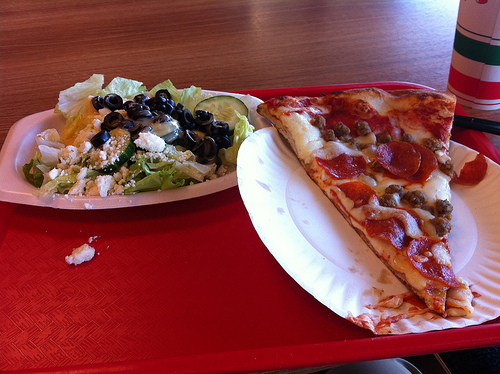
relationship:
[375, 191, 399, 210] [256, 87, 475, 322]
sausage on slice of pizza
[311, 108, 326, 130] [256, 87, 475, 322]
sausage on slice of pizza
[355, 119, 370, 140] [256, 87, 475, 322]
sausage on slice of pizza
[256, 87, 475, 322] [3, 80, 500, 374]
slice of pizza on tray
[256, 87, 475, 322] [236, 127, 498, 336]
slice of pizza on plate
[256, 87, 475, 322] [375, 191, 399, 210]
slice of pizza has sausage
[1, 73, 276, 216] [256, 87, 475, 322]
plate of salad next to slice of pizza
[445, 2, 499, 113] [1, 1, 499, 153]
cup sitting on table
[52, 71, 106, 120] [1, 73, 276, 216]
lettuce in plate of salad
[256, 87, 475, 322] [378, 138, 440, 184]
slice of pizza has pepperoni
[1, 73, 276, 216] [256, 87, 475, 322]
plate of salad to complement slice of pizza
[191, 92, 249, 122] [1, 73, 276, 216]
cucumber in plate of salad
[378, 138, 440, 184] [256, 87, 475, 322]
pepperoni on slice of pizza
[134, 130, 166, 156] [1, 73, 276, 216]
cheese on plate of salad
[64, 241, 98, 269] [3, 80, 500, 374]
cheese on tray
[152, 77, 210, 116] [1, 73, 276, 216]
lettuce in plate of salad